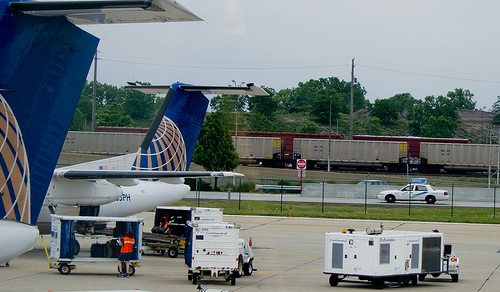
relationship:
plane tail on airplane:
[123, 80, 272, 171] [41, 81, 270, 258]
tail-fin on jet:
[0, 0, 201, 226] [0, 0, 206, 269]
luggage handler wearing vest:
[113, 224, 136, 275] [116, 237, 135, 257]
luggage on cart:
[88, 238, 121, 257] [49, 214, 145, 279]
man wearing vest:
[115, 231, 137, 278] [120, 235, 137, 254]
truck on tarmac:
[323, 223, 460, 289] [0, 216, 499, 291]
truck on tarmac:
[186, 218, 254, 282] [0, 216, 499, 291]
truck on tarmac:
[141, 206, 224, 257] [0, 216, 499, 291]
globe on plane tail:
[138, 117, 186, 174] [126, 79, 259, 177]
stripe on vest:
[121, 236, 135, 247] [115, 234, 137, 254]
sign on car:
[405, 177, 425, 187] [380, 182, 448, 202]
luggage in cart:
[88, 239, 120, 258] [45, 214, 145, 279]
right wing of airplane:
[39, 147, 266, 193] [41, 81, 270, 258]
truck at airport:
[185, 222, 256, 285] [4, 2, 498, 287]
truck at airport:
[323, 223, 460, 289] [4, 2, 498, 287]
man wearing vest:
[115, 222, 140, 274] [118, 240, 142, 258]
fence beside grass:
[189, 171, 498, 205] [192, 195, 498, 225]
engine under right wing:
[47, 176, 128, 211] [53, 169, 243, 187]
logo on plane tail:
[130, 116, 191, 168] [127, 86, 233, 176]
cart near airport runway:
[49, 214, 145, 279] [5, 212, 498, 288]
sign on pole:
[296, 157, 309, 171] [295, 169, 306, 182]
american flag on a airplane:
[96, 160, 109, 171] [41, 81, 270, 258]